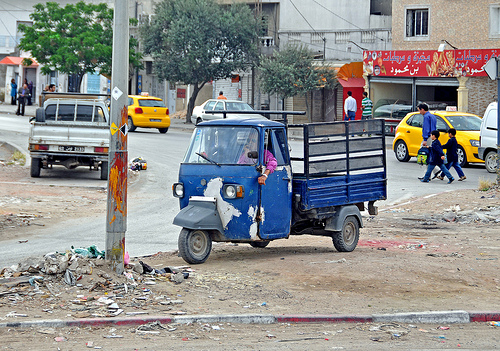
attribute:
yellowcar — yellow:
[389, 106, 486, 163]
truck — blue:
[171, 104, 397, 259]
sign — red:
[362, 50, 497, 82]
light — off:
[221, 183, 236, 200]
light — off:
[170, 180, 182, 199]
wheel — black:
[329, 214, 371, 251]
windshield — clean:
[178, 121, 263, 168]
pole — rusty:
[106, 1, 129, 262]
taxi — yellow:
[111, 91, 170, 135]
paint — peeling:
[195, 186, 260, 258]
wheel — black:
[314, 201, 369, 273]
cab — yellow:
[127, 89, 170, 134]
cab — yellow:
[392, 105, 489, 162]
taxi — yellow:
[98, 92, 178, 136]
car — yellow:
[122, 89, 170, 136]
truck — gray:
[34, 70, 148, 199]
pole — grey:
[99, 0, 136, 259]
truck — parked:
[20, 82, 137, 205]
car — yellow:
[391, 104, 488, 168]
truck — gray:
[25, 87, 143, 164]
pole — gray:
[104, 0, 128, 261]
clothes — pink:
[238, 142, 278, 172]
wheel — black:
[169, 217, 217, 263]